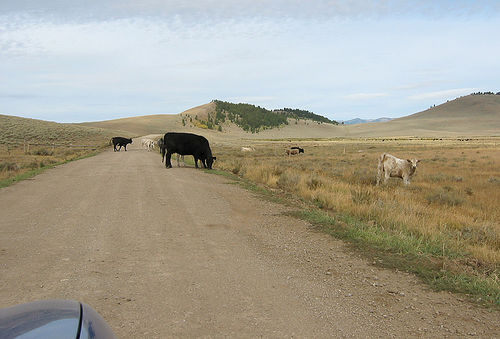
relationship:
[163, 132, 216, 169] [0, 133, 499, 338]
cow on road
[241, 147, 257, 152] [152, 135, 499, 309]
cow in field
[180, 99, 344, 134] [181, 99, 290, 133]
forest on hill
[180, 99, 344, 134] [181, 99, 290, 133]
forest on top of hill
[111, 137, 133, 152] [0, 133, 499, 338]
cow crossing road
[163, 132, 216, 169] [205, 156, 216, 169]
cow has head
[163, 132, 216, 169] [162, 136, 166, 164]
cow has tail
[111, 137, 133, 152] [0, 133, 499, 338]
cow on road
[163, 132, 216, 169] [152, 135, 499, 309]
cow eating field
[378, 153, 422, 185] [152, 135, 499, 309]
cow standing in field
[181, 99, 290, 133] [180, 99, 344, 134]
hill covered by forest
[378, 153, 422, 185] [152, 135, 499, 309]
cow in field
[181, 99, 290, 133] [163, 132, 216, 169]
hill behind cow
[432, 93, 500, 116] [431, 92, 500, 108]
hill covered by forest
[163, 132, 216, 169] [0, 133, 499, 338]
cow in road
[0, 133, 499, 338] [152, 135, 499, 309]
road next to field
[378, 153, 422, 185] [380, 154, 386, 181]
cow has tail